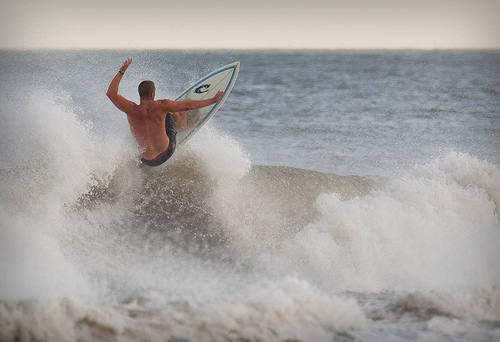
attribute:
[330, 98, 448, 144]
wave — pretty big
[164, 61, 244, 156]
surfboard — long white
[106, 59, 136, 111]
arm — bent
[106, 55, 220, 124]
arm — other , extended 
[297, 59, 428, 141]
ripples — small 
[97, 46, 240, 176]
man — no shirt 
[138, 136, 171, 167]
behind — sticking out